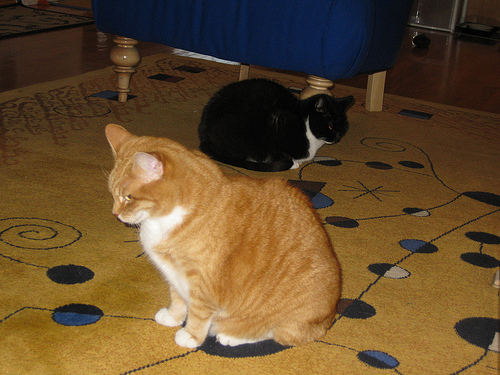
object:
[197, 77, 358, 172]
cat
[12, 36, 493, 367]
floor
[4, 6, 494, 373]
floor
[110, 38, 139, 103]
leg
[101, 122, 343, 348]
cat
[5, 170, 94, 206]
floor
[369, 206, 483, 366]
carpet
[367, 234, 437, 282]
patterns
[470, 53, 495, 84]
floors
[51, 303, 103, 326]
circle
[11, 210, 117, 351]
carpet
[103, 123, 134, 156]
ear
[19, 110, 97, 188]
carpet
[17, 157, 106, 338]
floor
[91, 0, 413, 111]
cushion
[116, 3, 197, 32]
couch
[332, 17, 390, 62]
cloth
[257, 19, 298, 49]
cloth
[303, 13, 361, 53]
cloth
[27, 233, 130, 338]
rug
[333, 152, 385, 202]
rug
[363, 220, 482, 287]
pattern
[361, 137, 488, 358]
rug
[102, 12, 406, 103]
furniture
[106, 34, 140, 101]
leg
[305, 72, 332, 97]
leg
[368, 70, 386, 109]
leg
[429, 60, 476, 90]
flooring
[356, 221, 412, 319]
rug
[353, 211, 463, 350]
rug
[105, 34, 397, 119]
legs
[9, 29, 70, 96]
floors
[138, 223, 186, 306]
chest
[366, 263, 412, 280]
dot